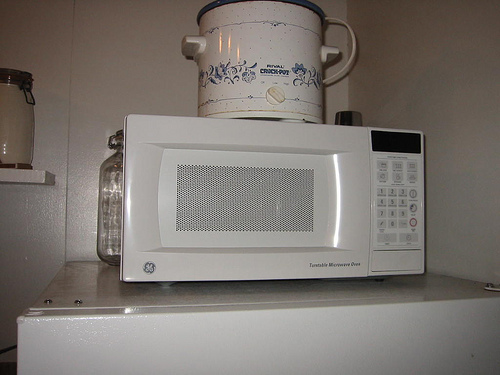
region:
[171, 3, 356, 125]
Slow cooker on top of microwave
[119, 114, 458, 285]
Microwave on top of refrigeratgor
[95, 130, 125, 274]
Mason jar on top of fridge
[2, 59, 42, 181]
Mason jar on shelf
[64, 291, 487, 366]
Refrigerator with items on it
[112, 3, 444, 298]
A pair of kitchen appliances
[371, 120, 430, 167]
Display of microwave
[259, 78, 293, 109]
Switch for slow cooker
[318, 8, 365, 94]
Cord of slow cooker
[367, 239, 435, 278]
Door button of microwave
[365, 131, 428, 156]
microwave lcd display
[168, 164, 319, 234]
microwave viewing window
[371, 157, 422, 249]
microwave control panel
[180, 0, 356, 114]
large white crock pot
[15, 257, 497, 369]
white and brown kitchen counter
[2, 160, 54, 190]
wall mounted shelf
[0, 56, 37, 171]
large jar on shelf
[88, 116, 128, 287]
left side of microwave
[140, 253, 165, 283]
microwave ge logo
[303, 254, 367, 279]
writing on microwave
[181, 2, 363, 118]
white and blue crock pot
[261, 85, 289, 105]
dial on crockpot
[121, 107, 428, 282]
white microwave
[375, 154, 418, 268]
dials on microwave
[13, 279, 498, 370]
top portion of a fridge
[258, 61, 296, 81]
crockpot logo on crockpot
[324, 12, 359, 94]
white electrical cord of crockpot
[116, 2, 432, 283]
crockpot sitting on microwave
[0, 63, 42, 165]
ceramic jar that is white with brown top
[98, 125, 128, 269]
jar placed behind microwave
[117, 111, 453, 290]
Microwave sitting on refrigerator.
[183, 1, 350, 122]
Crock pot sitting on microwave.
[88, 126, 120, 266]
Jar sitting next to microwave.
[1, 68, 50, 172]
Ceramic jar on shelf.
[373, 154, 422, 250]
Control pad for microwave.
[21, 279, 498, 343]
Top of a refrigerator.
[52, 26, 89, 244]
White wall of kitchen.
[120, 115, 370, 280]
A microwave oven door.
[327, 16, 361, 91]
Crock pot power cord.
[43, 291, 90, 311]
Screws in top of refrigerator.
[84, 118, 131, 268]
A clear storage jar.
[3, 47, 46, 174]
A tan storage container.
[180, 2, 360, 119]
A crock pot.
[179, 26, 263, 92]
The blue design on crockpot.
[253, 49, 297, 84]
Writing that says crock pot.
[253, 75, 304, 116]
Control knob for crock pot.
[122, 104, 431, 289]
A white microwave.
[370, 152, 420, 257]
Control panel for microwave.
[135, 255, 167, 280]
Company emblem saying GE.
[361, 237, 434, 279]
Button to open door of microwave.